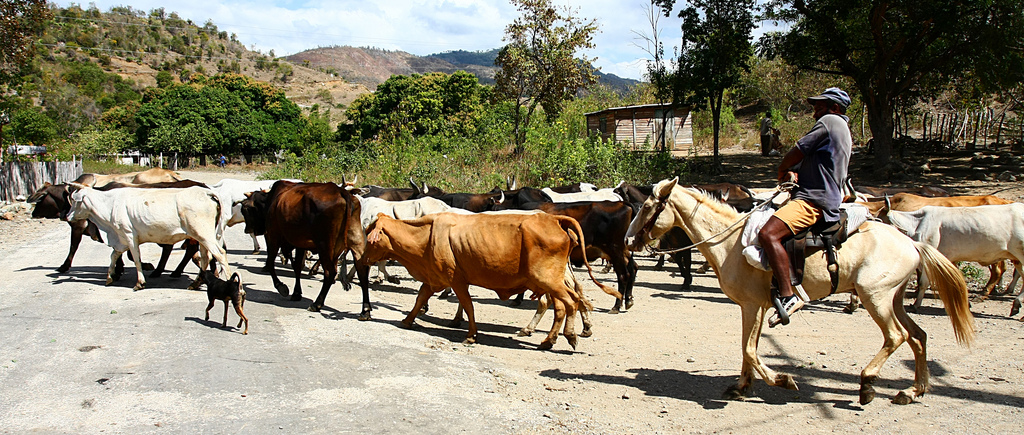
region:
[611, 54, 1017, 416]
Man riding horse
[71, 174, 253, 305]
White cow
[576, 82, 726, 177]
Shed behind a tree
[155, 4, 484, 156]
Trees with mountains in the distance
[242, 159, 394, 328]
Dark brown cow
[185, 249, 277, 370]
Small brown dog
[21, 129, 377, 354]
Five cows next to small dog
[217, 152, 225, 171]
Man wearing blue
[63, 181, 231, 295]
white cow being hurded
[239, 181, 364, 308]
brown cow being hurded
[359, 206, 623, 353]
tan cow being hurded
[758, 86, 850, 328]
a man hurding cows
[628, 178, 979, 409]
horse helping hurd cows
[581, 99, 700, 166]
a wooden shack surrounded by trees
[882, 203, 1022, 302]
white cow being hurded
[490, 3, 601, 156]
tree in a field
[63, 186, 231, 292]
A white cow walking down a path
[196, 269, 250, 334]
A small dog walking with the cows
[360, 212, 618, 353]
A light brown cow walking down a path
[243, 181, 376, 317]
A brown cow walking down a path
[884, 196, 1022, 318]
A white cow walking down a path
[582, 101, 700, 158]
A wooden shed on the side of a path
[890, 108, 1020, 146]
An old fence made of sticks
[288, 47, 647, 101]
A group of mountains in the distance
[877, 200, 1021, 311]
a cow in a field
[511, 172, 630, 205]
a cow in a field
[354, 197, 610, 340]
a cow in a field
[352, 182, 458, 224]
a cow in a field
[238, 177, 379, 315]
a cow in a field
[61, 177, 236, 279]
a cow in a field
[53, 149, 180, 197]
a cow in a field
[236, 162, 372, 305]
a cow in a field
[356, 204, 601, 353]
a cow in a field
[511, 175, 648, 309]
a cow in a field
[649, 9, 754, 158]
a tree in a field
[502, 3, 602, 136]
a tree in a field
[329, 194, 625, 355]
the cow is brown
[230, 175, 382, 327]
the cow is dark brown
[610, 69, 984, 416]
a man rides a horse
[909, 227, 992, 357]
the tail of the horse is long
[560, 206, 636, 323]
the tail is long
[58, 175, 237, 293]
the cow is white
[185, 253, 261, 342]
a dog on the road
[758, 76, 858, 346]
man on a horse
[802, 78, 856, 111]
baseball cap on a man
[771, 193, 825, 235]
tan shorts of a man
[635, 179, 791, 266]
reins of the horse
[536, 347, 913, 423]
shadow of the horse and rider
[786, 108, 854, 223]
blue shirt on the man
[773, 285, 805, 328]
left sneaker in the stirrup